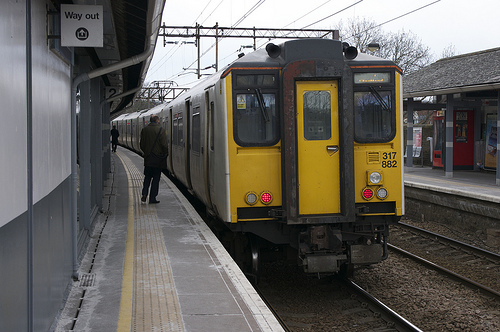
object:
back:
[224, 43, 401, 226]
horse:
[408, 46, 491, 98]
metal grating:
[80, 269, 95, 289]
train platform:
[96, 212, 206, 330]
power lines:
[170, 1, 455, 98]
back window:
[225, 70, 282, 145]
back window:
[346, 80, 399, 150]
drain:
[60, 210, 112, 330]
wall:
[0, 8, 77, 330]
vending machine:
[429, 102, 473, 172]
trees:
[331, 15, 454, 80]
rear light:
[366, 172, 386, 182]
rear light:
[358, 182, 377, 204]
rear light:
[375, 185, 388, 202]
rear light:
[259, 188, 273, 205]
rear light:
[245, 187, 259, 207]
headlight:
[243, 187, 262, 207]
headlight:
[258, 187, 273, 204]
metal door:
[297, 78, 339, 217]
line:
[112, 150, 134, 330]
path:
[117, 150, 184, 330]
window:
[302, 87, 333, 139]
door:
[293, 72, 347, 217]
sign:
[57, 3, 104, 47]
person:
[105, 122, 130, 154]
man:
[140, 110, 172, 208]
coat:
[140, 124, 170, 159]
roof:
[393, 52, 495, 101]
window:
[189, 98, 204, 153]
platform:
[50, 142, 285, 329]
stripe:
[114, 150, 134, 330]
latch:
[321, 143, 340, 155]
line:
[114, 192, 136, 327]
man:
[137, 114, 173, 213]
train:
[164, 92, 389, 219]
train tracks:
[344, 273, 406, 320]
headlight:
[368, 186, 373, 193]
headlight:
[375, 186, 389, 198]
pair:
[360, 185, 387, 198]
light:
[362, 187, 374, 198]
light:
[259, 190, 271, 202]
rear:
[227, 39, 403, 262]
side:
[111, 70, 229, 222]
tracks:
[397, 209, 498, 302]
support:
[443, 96, 458, 177]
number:
[380, 148, 397, 169]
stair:
[300, 248, 348, 278]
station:
[1, 1, 498, 330]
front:
[224, 57, 403, 227]